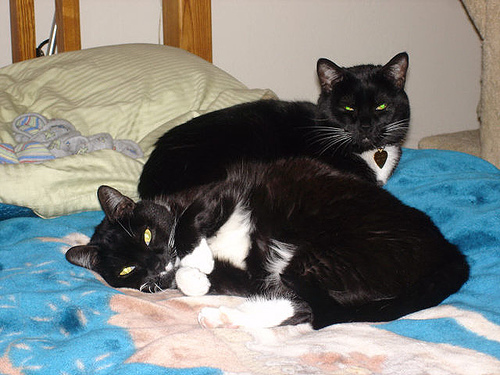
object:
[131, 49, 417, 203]
cats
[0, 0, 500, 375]
bed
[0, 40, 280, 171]
pillow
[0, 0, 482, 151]
wall